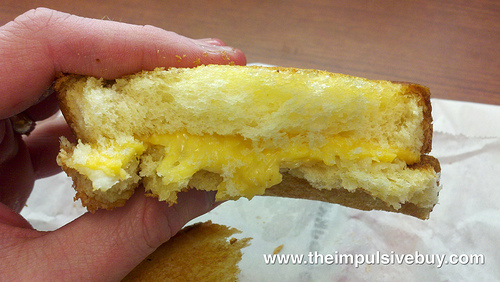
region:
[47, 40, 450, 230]
Piece of sandwich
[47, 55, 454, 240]
Sandwich has melted cheese inside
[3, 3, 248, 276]
Fingers holding a sandwich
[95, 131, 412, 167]
Melted cheese inside bread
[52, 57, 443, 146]
Bread on top of sandwich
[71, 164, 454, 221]
Bread holding melted cheese in sandwich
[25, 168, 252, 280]
Thump finger holding the lower slice of bread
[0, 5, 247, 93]
Index finger holding the sandwich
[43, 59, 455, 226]
Sandwich in middle of fingers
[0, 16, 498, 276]
Hand holding a sandwich over a white surface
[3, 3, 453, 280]
a hand holding a sandwich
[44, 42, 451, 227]
half of a sandwich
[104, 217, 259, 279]
a piece of a sandwich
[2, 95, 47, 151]
a wedding ring on the finger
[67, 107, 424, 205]
melted cheese in the middle of sandwich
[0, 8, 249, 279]
a hand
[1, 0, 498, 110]
the table is wooden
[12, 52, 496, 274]
a paper under the sandwich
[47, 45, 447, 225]
two slices of bread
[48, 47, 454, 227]
the bread is toasted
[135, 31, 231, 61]
crumbs on a finger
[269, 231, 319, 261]
crumbs on a white wrapper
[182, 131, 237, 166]
yellow cheese oozing from a sandwich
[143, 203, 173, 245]
folds in the skin of a thumb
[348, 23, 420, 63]
a brown wooden table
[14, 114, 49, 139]
a gold ring encircling a finger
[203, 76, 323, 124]
flaky white bread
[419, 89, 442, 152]
dark brown crust on bread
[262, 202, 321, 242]
oil stains on white paper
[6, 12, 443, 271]
white hand holding sandwich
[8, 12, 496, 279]
this is an indoor kitchen scene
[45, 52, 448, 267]
toasted yellow bread with yellow cheese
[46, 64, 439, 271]
sandwich with melted cheese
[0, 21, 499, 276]
sandwich against white paper wrapper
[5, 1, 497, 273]
hand holding sandwich over wooden counter top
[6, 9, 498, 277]
white paper bag over wooden table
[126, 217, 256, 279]
piece of torn bread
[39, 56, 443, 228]
toasted grilled cheese sandwich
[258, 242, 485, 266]
white writing on photograph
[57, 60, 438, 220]
a sandwich with scrambled egg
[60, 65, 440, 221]
two pieces of white bread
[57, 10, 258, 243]
two fingers holding an egg sandwich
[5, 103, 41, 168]
hand has an upside down diamond ring in it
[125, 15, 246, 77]
the fingers have short nails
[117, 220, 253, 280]
a part of the sandwich is below the hand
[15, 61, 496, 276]
the sandwich is above a piece of paper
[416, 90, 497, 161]
the paper is folded on the edge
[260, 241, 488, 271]
a website is located on the right lower edge of the photo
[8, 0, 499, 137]
the paper is on a wooden counter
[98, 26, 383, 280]
cheese on the sandwich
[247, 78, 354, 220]
bread that has been toasted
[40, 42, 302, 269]
a hand holding a bread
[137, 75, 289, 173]
cheese in between the rbead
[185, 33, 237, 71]
a finger on the hand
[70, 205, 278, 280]
a finger on the hand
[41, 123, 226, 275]
a finger on the hand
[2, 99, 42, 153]
a ring on the finger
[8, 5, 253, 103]
a human pointer finger